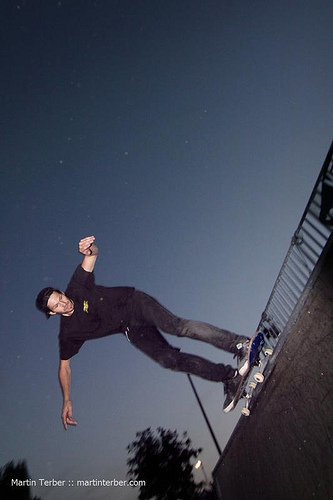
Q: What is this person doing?
A: Skateboarding.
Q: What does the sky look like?
A: Getting dark.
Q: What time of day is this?
A: Twilight.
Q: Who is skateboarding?
A: A man.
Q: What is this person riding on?
A: A skateboard.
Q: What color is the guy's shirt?
A: Black.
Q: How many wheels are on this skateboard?
A: Four.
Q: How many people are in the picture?
A: One.